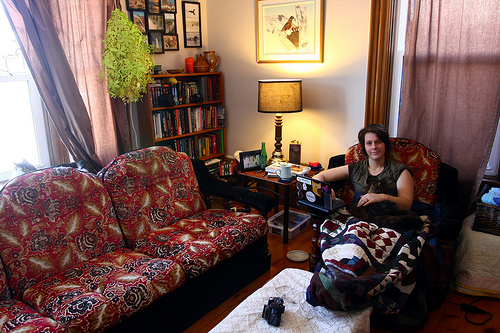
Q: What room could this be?
A: It is a living room.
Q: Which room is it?
A: It is a living room.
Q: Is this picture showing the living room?
A: Yes, it is showing the living room.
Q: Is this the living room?
A: Yes, it is the living room.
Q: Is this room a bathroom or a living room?
A: It is a living room.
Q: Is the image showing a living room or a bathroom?
A: It is showing a living room.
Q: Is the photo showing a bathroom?
A: No, the picture is showing a living room.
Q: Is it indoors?
A: Yes, it is indoors.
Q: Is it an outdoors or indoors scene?
A: It is indoors.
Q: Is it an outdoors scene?
A: No, it is indoors.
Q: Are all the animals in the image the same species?
A: No, they are birds and cats.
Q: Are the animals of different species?
A: Yes, they are birds and cats.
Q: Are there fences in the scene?
A: No, there are no fences.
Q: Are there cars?
A: No, there are no cars.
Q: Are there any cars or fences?
A: No, there are no cars or fences.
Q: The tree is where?
A: The tree is in the living room.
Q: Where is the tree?
A: The tree is in the living room.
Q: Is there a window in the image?
A: Yes, there is a window.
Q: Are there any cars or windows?
A: Yes, there is a window.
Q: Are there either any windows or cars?
A: Yes, there is a window.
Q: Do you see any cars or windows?
A: Yes, there is a window.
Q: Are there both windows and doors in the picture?
A: No, there is a window but no doors.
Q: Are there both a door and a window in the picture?
A: No, there is a window but no doors.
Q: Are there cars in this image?
A: No, there are no cars.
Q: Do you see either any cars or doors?
A: No, there are no cars or doors.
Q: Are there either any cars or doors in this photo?
A: No, there are no cars or doors.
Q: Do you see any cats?
A: Yes, there is a cat.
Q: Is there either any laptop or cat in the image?
A: Yes, there is a cat.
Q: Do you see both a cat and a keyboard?
A: No, there is a cat but no keyboards.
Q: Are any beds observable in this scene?
A: No, there are no beds.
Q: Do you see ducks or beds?
A: No, there are no beds or ducks.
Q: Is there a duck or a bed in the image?
A: No, there are no beds or ducks.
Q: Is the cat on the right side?
A: Yes, the cat is on the right of the image.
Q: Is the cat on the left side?
A: No, the cat is on the right of the image.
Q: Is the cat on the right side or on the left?
A: The cat is on the right of the image.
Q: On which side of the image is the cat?
A: The cat is on the right of the image.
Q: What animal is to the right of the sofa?
A: The animal is a cat.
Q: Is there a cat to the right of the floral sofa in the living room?
A: Yes, there is a cat to the right of the sofa.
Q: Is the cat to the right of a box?
A: No, the cat is to the right of the sofa.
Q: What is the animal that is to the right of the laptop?
A: The animal is a cat.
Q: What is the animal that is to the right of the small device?
A: The animal is a cat.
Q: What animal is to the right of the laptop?
A: The animal is a cat.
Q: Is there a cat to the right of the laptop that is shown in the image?
A: Yes, there is a cat to the right of the laptop.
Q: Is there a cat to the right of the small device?
A: Yes, there is a cat to the right of the laptop.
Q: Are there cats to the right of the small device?
A: Yes, there is a cat to the right of the laptop.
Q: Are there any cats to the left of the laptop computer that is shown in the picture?
A: No, the cat is to the right of the laptop computer.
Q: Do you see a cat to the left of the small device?
A: No, the cat is to the right of the laptop computer.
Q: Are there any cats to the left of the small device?
A: No, the cat is to the right of the laptop computer.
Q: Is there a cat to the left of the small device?
A: No, the cat is to the right of the laptop computer.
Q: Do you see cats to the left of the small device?
A: No, the cat is to the right of the laptop computer.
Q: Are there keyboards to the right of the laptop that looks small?
A: No, there is a cat to the right of the laptop.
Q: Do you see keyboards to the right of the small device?
A: No, there is a cat to the right of the laptop.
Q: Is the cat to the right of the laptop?
A: Yes, the cat is to the right of the laptop.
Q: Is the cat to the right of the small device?
A: Yes, the cat is to the right of the laptop.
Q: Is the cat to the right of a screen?
A: No, the cat is to the right of the laptop.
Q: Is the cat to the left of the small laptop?
A: No, the cat is to the right of the laptop.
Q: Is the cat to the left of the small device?
A: No, the cat is to the right of the laptop.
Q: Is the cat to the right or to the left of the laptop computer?
A: The cat is to the right of the laptop computer.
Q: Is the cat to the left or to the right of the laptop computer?
A: The cat is to the right of the laptop computer.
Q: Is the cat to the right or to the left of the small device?
A: The cat is to the right of the laptop computer.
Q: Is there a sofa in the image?
A: Yes, there is a sofa.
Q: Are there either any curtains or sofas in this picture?
A: Yes, there is a sofa.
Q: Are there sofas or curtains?
A: Yes, there is a sofa.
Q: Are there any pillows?
A: No, there are no pillows.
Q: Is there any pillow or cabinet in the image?
A: No, there are no pillows or cabinets.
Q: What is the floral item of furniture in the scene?
A: The piece of furniture is a sofa.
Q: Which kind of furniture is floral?
A: The furniture is a sofa.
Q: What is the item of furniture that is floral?
A: The piece of furniture is a sofa.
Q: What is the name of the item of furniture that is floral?
A: The piece of furniture is a sofa.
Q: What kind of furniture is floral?
A: The furniture is a sofa.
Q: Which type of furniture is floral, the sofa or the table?
A: The sofa is floral.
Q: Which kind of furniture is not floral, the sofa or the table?
A: The table is not floral.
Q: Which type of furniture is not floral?
A: The furniture is a table.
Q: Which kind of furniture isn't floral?
A: The furniture is a table.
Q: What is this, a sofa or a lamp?
A: This is a sofa.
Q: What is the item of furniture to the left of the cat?
A: The piece of furniture is a sofa.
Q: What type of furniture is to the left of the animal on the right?
A: The piece of furniture is a sofa.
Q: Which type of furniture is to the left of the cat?
A: The piece of furniture is a sofa.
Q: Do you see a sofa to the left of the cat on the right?
A: Yes, there is a sofa to the left of the cat.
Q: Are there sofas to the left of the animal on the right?
A: Yes, there is a sofa to the left of the cat.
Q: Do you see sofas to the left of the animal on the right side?
A: Yes, there is a sofa to the left of the cat.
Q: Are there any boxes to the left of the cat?
A: No, there is a sofa to the left of the cat.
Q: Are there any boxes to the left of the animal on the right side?
A: No, there is a sofa to the left of the cat.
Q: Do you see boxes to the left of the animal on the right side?
A: No, there is a sofa to the left of the cat.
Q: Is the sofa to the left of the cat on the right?
A: Yes, the sofa is to the left of the cat.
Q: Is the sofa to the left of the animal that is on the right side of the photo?
A: Yes, the sofa is to the left of the cat.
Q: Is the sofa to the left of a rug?
A: No, the sofa is to the left of the cat.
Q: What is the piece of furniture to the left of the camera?
A: The piece of furniture is a sofa.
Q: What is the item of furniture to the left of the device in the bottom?
A: The piece of furniture is a sofa.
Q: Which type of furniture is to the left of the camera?
A: The piece of furniture is a sofa.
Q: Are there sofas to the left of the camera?
A: Yes, there is a sofa to the left of the camera.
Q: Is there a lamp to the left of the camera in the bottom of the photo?
A: No, there is a sofa to the left of the camera.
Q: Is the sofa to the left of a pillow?
A: No, the sofa is to the left of a camera.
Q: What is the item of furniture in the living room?
A: The piece of furniture is a sofa.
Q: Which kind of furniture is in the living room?
A: The piece of furniture is a sofa.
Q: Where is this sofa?
A: The sofa is in the living room.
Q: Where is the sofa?
A: The sofa is in the living room.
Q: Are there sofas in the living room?
A: Yes, there is a sofa in the living room.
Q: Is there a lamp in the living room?
A: No, there is a sofa in the living room.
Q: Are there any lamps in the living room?
A: No, there is a sofa in the living room.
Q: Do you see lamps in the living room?
A: No, there is a sofa in the living room.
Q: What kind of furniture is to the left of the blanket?
A: The piece of furniture is a sofa.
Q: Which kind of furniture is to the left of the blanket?
A: The piece of furniture is a sofa.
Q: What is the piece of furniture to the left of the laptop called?
A: The piece of furniture is a sofa.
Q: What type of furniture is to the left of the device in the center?
A: The piece of furniture is a sofa.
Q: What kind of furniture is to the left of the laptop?
A: The piece of furniture is a sofa.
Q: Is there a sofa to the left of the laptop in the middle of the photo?
A: Yes, there is a sofa to the left of the laptop computer.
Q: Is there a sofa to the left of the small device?
A: Yes, there is a sofa to the left of the laptop computer.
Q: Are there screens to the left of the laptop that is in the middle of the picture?
A: No, there is a sofa to the left of the laptop.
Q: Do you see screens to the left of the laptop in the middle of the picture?
A: No, there is a sofa to the left of the laptop.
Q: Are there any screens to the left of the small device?
A: No, there is a sofa to the left of the laptop.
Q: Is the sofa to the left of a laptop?
A: Yes, the sofa is to the left of a laptop.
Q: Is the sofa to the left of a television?
A: No, the sofa is to the left of a laptop.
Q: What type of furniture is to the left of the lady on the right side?
A: The piece of furniture is a sofa.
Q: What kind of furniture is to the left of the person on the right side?
A: The piece of furniture is a sofa.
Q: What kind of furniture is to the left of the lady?
A: The piece of furniture is a sofa.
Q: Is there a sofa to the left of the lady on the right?
A: Yes, there is a sofa to the left of the lady.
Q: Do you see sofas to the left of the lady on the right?
A: Yes, there is a sofa to the left of the lady.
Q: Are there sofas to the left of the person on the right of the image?
A: Yes, there is a sofa to the left of the lady.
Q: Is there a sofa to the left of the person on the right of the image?
A: Yes, there is a sofa to the left of the lady.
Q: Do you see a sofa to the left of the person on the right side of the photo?
A: Yes, there is a sofa to the left of the lady.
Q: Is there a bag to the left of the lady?
A: No, there is a sofa to the left of the lady.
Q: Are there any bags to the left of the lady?
A: No, there is a sofa to the left of the lady.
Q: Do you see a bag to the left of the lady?
A: No, there is a sofa to the left of the lady.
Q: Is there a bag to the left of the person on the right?
A: No, there is a sofa to the left of the lady.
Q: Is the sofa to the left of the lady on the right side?
A: Yes, the sofa is to the left of the lady.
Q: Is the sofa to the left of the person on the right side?
A: Yes, the sofa is to the left of the lady.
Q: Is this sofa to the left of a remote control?
A: No, the sofa is to the left of the lady.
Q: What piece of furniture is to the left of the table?
A: The piece of furniture is a sofa.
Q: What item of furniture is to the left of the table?
A: The piece of furniture is a sofa.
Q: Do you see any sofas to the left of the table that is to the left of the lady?
A: Yes, there is a sofa to the left of the table.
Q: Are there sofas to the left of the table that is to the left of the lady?
A: Yes, there is a sofa to the left of the table.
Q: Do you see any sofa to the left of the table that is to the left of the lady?
A: Yes, there is a sofa to the left of the table.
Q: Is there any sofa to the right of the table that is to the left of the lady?
A: No, the sofa is to the left of the table.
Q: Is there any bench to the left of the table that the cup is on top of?
A: No, there is a sofa to the left of the table.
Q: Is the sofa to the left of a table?
A: Yes, the sofa is to the left of a table.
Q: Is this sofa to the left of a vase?
A: No, the sofa is to the left of a table.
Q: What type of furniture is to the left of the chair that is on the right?
A: The piece of furniture is a sofa.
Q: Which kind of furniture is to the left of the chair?
A: The piece of furniture is a sofa.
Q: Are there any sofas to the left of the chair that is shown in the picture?
A: Yes, there is a sofa to the left of the chair.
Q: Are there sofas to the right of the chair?
A: No, the sofa is to the left of the chair.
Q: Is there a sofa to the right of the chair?
A: No, the sofa is to the left of the chair.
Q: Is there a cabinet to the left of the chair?
A: No, there is a sofa to the left of the chair.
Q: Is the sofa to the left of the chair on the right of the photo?
A: Yes, the sofa is to the left of the chair.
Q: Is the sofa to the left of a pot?
A: No, the sofa is to the left of the chair.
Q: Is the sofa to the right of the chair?
A: No, the sofa is to the left of the chair.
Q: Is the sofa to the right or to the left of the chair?
A: The sofa is to the left of the chair.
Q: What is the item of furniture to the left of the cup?
A: The piece of furniture is a sofa.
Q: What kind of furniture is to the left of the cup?
A: The piece of furniture is a sofa.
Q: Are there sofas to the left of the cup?
A: Yes, there is a sofa to the left of the cup.